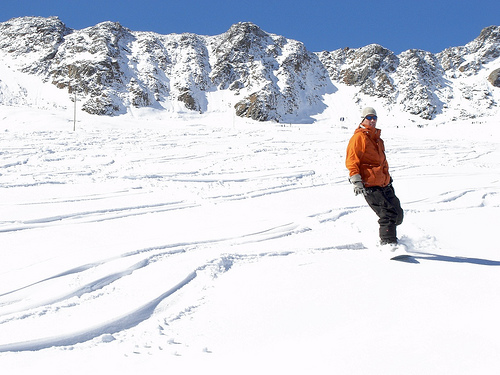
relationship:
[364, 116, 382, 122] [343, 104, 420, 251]
sunglasses on man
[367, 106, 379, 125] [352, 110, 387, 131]
beanie on head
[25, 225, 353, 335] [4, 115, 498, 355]
tracks on snow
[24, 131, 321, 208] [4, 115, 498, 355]
tracks on snow